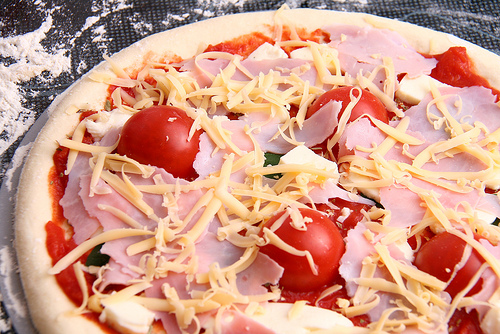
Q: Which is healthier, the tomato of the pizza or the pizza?
A: The tomato is healthier than the pizza.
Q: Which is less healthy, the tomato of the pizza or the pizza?
A: The pizza is less healthy than the tomato.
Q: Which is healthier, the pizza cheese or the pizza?
A: The cheese is healthier than the pizza.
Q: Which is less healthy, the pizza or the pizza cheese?
A: The pizza is less healthy than the cheese.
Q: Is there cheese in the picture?
A: Yes, there is cheese.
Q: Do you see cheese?
A: Yes, there is cheese.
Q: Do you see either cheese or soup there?
A: Yes, there is cheese.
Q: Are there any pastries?
A: No, there are no pastries.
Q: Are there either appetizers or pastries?
A: No, there are no pastries or appetizers.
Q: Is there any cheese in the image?
A: Yes, there is cheese.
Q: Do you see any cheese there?
A: Yes, there is cheese.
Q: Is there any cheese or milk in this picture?
A: Yes, there is cheese.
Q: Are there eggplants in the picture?
A: No, there are no eggplants.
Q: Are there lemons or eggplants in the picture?
A: No, there are no eggplants or lemons.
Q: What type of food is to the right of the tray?
A: The food is cheese.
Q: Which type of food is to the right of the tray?
A: The food is cheese.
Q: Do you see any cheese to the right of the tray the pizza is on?
A: Yes, there is cheese to the right of the tray.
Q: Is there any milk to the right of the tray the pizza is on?
A: No, there is cheese to the right of the tray.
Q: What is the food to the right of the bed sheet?
A: The food is cheese.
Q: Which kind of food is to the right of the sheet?
A: The food is cheese.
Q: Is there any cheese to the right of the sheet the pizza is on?
A: Yes, there is cheese to the right of the sheet.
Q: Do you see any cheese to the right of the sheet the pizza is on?
A: Yes, there is cheese to the right of the sheet.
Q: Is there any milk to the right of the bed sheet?
A: No, there is cheese to the right of the bed sheet.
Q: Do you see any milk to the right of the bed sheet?
A: No, there is cheese to the right of the bed sheet.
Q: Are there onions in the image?
A: Yes, there is an onion.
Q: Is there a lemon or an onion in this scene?
A: Yes, there is an onion.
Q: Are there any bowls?
A: No, there are no bowls.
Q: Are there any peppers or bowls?
A: No, there are no bowls or peppers.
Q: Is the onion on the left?
A: Yes, the onion is on the left of the image.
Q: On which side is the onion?
A: The onion is on the left of the image.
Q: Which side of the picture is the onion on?
A: The onion is on the left of the image.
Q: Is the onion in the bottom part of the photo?
A: Yes, the onion is in the bottom of the image.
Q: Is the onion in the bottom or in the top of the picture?
A: The onion is in the bottom of the image.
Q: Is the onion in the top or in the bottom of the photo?
A: The onion is in the bottom of the image.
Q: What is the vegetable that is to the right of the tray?
A: The vegetable is an onion.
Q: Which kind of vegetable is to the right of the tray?
A: The vegetable is an onion.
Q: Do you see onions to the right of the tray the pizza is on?
A: Yes, there is an onion to the right of the tray.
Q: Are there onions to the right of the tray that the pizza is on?
A: Yes, there is an onion to the right of the tray.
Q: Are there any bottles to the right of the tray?
A: No, there is an onion to the right of the tray.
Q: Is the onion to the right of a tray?
A: Yes, the onion is to the right of a tray.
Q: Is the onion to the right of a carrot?
A: No, the onion is to the right of a tray.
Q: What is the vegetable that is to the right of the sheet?
A: The vegetable is an onion.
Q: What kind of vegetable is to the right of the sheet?
A: The vegetable is an onion.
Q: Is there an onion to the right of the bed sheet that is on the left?
A: Yes, there is an onion to the right of the bed sheet.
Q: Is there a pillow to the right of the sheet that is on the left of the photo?
A: No, there is an onion to the right of the sheet.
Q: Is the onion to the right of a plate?
A: No, the onion is to the right of the sheet.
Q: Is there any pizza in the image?
A: Yes, there is a pizza.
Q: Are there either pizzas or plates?
A: Yes, there is a pizza.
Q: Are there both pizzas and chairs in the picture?
A: No, there is a pizza but no chairs.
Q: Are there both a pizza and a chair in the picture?
A: No, there is a pizza but no chairs.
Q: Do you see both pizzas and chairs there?
A: No, there is a pizza but no chairs.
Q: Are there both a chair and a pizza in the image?
A: No, there is a pizza but no chairs.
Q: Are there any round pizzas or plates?
A: Yes, there is a round pizza.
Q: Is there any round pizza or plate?
A: Yes, there is a round pizza.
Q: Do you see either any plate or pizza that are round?
A: Yes, the pizza is round.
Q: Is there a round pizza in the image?
A: Yes, there is a round pizza.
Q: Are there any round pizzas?
A: Yes, there is a round pizza.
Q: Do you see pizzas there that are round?
A: Yes, there is a round pizza.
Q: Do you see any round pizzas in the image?
A: Yes, there is a round pizza.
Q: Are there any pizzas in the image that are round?
A: Yes, there is a pizza that is round.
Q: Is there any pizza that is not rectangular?
A: Yes, there is a round pizza.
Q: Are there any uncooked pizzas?
A: Yes, there is an uncooked pizza.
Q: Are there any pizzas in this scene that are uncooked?
A: Yes, there is a pizza that is uncooked.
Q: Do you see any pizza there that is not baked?
A: Yes, there is a uncooked pizza.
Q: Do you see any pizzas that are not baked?
A: Yes, there is a uncooked pizza.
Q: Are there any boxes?
A: No, there are no boxes.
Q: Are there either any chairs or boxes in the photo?
A: No, there are no boxes or chairs.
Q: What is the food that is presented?
A: The food is a pizza.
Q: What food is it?
A: The food is a pizza.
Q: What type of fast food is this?
A: This is a pizza.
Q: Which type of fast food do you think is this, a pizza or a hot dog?
A: This is a pizza.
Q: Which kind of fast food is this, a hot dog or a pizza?
A: This is a pizza.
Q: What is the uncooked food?
A: The food is a pizza.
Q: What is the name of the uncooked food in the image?
A: The food is a pizza.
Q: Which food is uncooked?
A: The food is a pizza.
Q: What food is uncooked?
A: The food is a pizza.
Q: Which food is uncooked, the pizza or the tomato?
A: The pizza is uncooked.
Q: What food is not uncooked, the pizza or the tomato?
A: The tomato is not uncooked.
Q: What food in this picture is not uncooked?
A: The food is a tomato.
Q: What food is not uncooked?
A: The food is a tomato.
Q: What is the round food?
A: The food is a pizza.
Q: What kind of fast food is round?
A: The fast food is a pizza.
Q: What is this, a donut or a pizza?
A: This is a pizza.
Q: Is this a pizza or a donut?
A: This is a pizza.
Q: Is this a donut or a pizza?
A: This is a pizza.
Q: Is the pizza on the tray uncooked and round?
A: Yes, the pizza is uncooked and round.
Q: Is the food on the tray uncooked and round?
A: Yes, the pizza is uncooked and round.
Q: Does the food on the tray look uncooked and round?
A: Yes, the pizza is uncooked and round.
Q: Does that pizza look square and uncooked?
A: No, the pizza is uncooked but round.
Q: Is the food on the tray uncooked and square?
A: No, the pizza is uncooked but round.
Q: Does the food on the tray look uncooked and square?
A: No, the pizza is uncooked but round.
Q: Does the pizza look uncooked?
A: Yes, the pizza is uncooked.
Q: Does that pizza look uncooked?
A: Yes, the pizza is uncooked.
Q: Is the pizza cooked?
A: No, the pizza is uncooked.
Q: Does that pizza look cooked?
A: No, the pizza is uncooked.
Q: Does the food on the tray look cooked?
A: No, the pizza is uncooked.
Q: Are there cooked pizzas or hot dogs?
A: No, there is a pizza but it is uncooked.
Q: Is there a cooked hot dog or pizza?
A: No, there is a pizza but it is uncooked.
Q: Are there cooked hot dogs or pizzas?
A: No, there is a pizza but it is uncooked.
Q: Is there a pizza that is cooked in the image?
A: No, there is a pizza but it is uncooked.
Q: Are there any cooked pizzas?
A: No, there is a pizza but it is uncooked.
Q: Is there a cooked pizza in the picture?
A: No, there is a pizza but it is uncooked.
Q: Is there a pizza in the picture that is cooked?
A: No, there is a pizza but it is uncooked.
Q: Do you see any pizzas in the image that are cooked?
A: No, there is a pizza but it is uncooked.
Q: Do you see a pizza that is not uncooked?
A: No, there is a pizza but it is uncooked.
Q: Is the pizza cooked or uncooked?
A: The pizza is uncooked.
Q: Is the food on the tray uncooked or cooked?
A: The pizza is uncooked.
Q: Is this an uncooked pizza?
A: Yes, this is an uncooked pizza.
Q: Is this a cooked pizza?
A: No, this is an uncooked pizza.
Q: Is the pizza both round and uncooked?
A: Yes, the pizza is round and uncooked.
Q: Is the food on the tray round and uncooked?
A: Yes, the pizza is round and uncooked.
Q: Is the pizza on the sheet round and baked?
A: No, the pizza is round but uncooked.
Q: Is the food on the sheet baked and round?
A: No, the pizza is round but uncooked.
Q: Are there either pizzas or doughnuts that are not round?
A: No, there is a pizza but it is round.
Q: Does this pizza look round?
A: Yes, the pizza is round.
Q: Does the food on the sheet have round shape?
A: Yes, the pizza is round.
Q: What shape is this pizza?
A: The pizza is round.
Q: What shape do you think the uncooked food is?
A: The pizza is round.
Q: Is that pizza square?
A: No, the pizza is round.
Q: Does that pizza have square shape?
A: No, the pizza is round.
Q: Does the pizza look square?
A: No, the pizza is round.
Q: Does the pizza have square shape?
A: No, the pizza is round.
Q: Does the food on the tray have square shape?
A: No, the pizza is round.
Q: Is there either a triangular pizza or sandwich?
A: No, there is a pizza but it is round.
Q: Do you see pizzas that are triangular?
A: No, there is a pizza but it is round.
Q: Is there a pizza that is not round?
A: No, there is a pizza but it is round.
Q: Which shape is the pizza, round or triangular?
A: The pizza is round.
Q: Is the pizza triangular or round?
A: The pizza is round.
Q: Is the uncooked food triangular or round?
A: The pizza is round.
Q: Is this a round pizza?
A: Yes, this is a round pizza.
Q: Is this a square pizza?
A: No, this is a round pizza.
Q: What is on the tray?
A: The pizza is on the tray.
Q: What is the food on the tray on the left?
A: The food is a pizza.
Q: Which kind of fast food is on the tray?
A: The food is a pizza.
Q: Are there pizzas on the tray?
A: Yes, there is a pizza on the tray.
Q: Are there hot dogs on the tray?
A: No, there is a pizza on the tray.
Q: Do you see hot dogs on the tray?
A: No, there is a pizza on the tray.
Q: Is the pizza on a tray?
A: Yes, the pizza is on a tray.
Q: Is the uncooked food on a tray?
A: Yes, the pizza is on a tray.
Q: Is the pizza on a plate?
A: No, the pizza is on a tray.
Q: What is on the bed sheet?
A: The pizza is on the bed sheet.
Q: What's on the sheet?
A: The pizza is on the bed sheet.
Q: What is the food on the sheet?
A: The food is a pizza.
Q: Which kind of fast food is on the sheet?
A: The food is a pizza.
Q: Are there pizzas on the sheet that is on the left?
A: Yes, there is a pizza on the bed sheet.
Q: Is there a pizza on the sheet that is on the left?
A: Yes, there is a pizza on the bed sheet.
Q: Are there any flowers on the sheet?
A: No, there is a pizza on the sheet.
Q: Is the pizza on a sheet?
A: Yes, the pizza is on a sheet.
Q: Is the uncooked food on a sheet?
A: Yes, the pizza is on a sheet.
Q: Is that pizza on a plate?
A: No, the pizza is on a sheet.